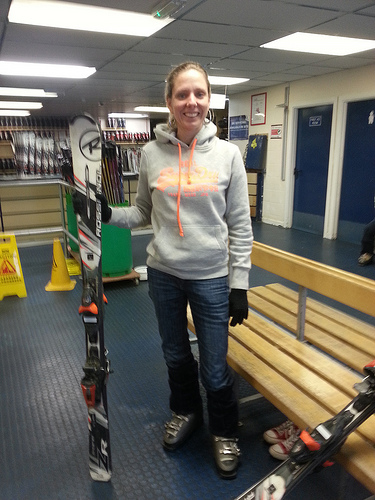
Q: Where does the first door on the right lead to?
A: Men's room.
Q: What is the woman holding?
A: Skis.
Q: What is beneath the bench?
A: Shoes.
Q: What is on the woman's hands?
A: Gloves.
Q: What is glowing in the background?
A: Lights.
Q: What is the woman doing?
A: Holding a ski.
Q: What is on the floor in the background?
A: Wet floor signs.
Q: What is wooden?
A: The bench.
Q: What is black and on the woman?
A: Gloves.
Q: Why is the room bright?
A: Lights.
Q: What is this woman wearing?
A: A grey sweater and blue jeans.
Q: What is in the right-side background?
A: Two blue doors with white frames.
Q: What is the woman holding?
A: A black, white, and orange ski.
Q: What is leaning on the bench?
A: A black, white, and orange ski.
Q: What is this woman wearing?
A: Blue jeans, and a grey hoodie with a neon-orange design.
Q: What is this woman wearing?
A: Blue jeans and a grey pullover.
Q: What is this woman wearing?
A: A grey sweater and blue jeans.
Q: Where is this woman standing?
A: Next to a wooden bench.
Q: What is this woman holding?
A: A ski.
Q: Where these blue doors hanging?
A: In a white wall.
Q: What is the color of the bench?
A: Brown.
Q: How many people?
A: 1.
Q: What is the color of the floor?
A: Blue.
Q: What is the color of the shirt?
A: Grey.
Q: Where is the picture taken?
A: At the ski shop.